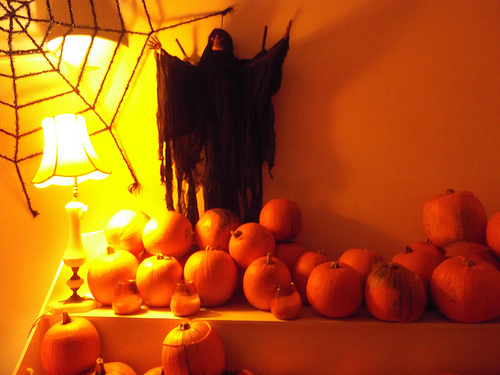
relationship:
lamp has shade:
[26, 104, 114, 314] [31, 97, 116, 194]